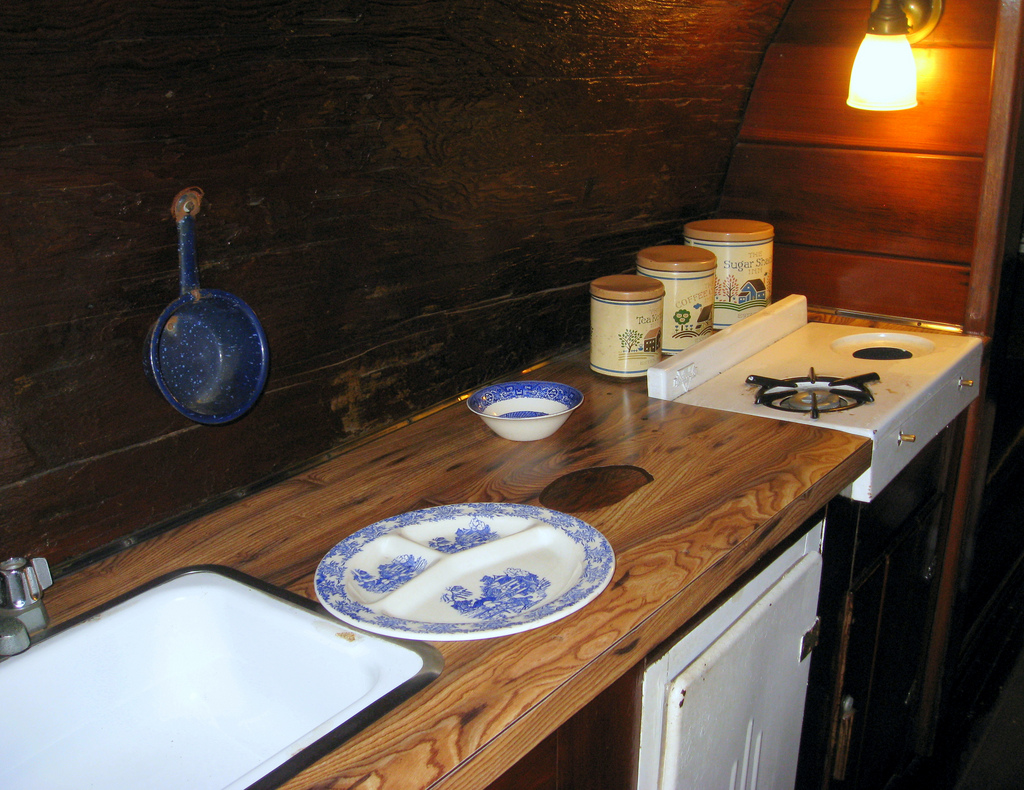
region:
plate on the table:
[324, 505, 552, 630]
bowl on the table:
[456, 373, 559, 451]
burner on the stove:
[854, 337, 915, 357]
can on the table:
[574, 281, 657, 373]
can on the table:
[658, 244, 722, 344]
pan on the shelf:
[143, 203, 245, 407]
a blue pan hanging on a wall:
[156, 175, 274, 435]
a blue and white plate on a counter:
[304, 497, 640, 634]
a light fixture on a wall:
[836, 3, 955, 112]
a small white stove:
[640, 291, 977, 500]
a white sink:
[0, 556, 463, 788]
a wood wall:
[327, 54, 651, 248]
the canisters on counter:
[583, 203, 793, 391]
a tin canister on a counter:
[583, 272, 666, 384]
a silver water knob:
[0, 541, 57, 631]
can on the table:
[574, 268, 650, 374]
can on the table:
[705, 224, 770, 314]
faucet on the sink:
[13, 597, 46, 630]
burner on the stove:
[766, 361, 844, 410]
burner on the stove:
[867, 331, 919, 366]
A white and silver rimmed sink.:
[15, 553, 437, 788]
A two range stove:
[658, 291, 981, 487]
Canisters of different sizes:
[571, 218, 807, 393]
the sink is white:
[2, 552, 423, 786]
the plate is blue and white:
[307, 487, 618, 643]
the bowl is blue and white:
[453, 374, 578, 435]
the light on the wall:
[832, 1, 944, 116]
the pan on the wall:
[143, 184, 276, 435]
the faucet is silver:
[0, 544, 62, 661]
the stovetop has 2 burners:
[672, 298, 990, 504]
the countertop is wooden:
[0, 326, 880, 782]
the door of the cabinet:
[646, 550, 817, 784]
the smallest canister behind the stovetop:
[580, 264, 667, 381]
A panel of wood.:
[717, 141, 992, 260]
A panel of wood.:
[735, 239, 991, 329]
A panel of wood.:
[727, 38, 1003, 147]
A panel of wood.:
[784, 0, 1001, 46]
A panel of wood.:
[960, 605, 1018, 730]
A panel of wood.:
[28, 14, 809, 85]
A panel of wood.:
[49, 67, 743, 160]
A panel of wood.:
[10, 157, 744, 275]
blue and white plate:
[310, 496, 617, 648]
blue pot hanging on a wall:
[146, 181, 273, 431]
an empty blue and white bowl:
[462, 377, 586, 442]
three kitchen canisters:
[585, 196, 779, 381]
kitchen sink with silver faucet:
[4, 535, 448, 788]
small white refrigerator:
[644, 505, 829, 787]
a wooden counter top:
[0, 370, 876, 788]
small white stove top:
[644, 281, 986, 782]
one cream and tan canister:
[584, 269, 667, 377]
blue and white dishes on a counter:
[309, 372, 622, 644]